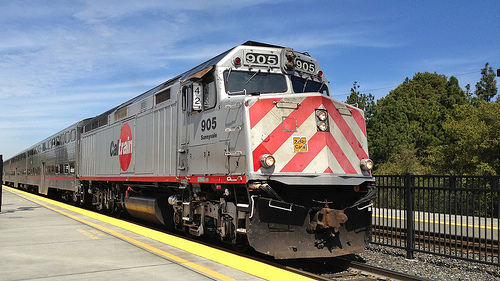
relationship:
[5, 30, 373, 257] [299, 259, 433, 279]
train travels on tracks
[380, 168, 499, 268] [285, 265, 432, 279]
fence near tracks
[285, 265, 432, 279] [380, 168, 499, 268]
tracks are near fence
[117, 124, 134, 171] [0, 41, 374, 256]
circle on locomotive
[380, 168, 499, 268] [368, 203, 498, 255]
fence separating highway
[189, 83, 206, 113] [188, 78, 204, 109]
number on mirror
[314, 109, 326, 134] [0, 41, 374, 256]
headlight on locomotive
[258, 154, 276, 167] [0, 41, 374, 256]
headlight on locomotive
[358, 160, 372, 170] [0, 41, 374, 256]
headlight on locomotive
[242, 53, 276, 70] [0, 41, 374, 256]
number on locomotive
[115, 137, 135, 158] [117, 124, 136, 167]
word in circle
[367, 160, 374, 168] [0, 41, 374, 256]
headlight on locomotive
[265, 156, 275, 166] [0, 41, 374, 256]
headlight on locomotive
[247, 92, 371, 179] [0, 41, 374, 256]
stripes on locomotive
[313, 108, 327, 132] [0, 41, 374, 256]
headlight front of locomotive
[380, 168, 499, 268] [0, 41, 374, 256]
fence next to locomotive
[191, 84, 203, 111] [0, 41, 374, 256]
number on locomotive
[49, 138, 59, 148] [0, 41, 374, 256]
window on locomotive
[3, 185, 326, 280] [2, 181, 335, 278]
stripe on platform